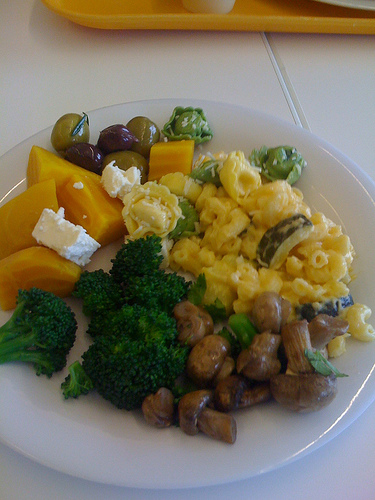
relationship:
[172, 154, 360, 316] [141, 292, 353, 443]
macaroni and cheese next to mushrooms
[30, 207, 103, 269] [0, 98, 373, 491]
feta cheese on top of plate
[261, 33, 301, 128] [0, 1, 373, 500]
caulk visible on table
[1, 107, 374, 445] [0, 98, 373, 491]
food on top of plate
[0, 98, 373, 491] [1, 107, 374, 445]
plate under food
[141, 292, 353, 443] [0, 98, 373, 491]
mushrooms on top of plate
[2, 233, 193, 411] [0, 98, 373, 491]
broccoli on top of plate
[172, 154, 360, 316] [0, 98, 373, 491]
macaroni and cheese on top of plate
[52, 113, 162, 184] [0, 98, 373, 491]
olives on top of plate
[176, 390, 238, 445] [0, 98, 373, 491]
mushroom on top of plate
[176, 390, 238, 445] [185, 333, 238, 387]
mushroom next to mushroom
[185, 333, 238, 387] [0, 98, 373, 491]
mushroom on top of plate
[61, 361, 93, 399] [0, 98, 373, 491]
broccoli floret on top of plate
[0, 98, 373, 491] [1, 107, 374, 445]
plate of food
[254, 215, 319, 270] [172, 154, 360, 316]
vegetable on top of macaroni and cheese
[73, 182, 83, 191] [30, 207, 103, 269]
crumb of feta cheese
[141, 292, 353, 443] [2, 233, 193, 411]
mushrooms next to broccoli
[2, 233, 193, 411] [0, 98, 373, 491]
broccoli on to of plate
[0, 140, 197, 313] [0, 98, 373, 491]
winter squash on top of plate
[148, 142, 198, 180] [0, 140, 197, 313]
chunk of winter squash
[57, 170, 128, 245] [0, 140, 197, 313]
chunk of winter squash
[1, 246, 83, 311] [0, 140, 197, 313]
chunk of winter squash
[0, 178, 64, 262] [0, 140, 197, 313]
chunk of winter squash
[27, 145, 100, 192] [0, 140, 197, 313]
chunk of winter squash